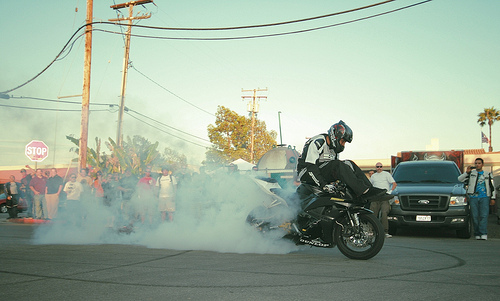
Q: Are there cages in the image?
A: No, there are no cages.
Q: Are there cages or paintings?
A: No, there are no cages or paintings.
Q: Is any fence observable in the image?
A: No, there are no fences.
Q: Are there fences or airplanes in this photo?
A: No, there are no fences or airplanes.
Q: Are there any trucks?
A: Yes, there is a truck.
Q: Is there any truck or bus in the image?
A: Yes, there is a truck.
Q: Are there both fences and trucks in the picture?
A: No, there is a truck but no fences.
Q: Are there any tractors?
A: No, there are no tractors.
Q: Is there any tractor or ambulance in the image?
A: No, there are no tractors or ambulances.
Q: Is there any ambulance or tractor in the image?
A: No, there are no tractors or ambulances.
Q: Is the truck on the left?
A: No, the truck is on the right of the image.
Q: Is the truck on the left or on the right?
A: The truck is on the right of the image.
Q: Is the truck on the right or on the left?
A: The truck is on the right of the image.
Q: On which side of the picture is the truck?
A: The truck is on the right of the image.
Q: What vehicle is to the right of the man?
A: The vehicle is a truck.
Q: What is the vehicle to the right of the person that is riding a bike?
A: The vehicle is a truck.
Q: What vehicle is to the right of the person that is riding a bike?
A: The vehicle is a truck.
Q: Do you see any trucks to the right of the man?
A: Yes, there is a truck to the right of the man.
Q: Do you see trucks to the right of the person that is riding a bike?
A: Yes, there is a truck to the right of the man.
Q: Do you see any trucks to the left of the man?
A: No, the truck is to the right of the man.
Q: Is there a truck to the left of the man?
A: No, the truck is to the right of the man.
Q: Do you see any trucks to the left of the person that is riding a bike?
A: No, the truck is to the right of the man.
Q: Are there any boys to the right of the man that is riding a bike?
A: No, there is a truck to the right of the man.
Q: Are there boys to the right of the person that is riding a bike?
A: No, there is a truck to the right of the man.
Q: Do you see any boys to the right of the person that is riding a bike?
A: No, there is a truck to the right of the man.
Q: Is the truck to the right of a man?
A: Yes, the truck is to the right of a man.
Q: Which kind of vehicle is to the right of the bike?
A: The vehicle is a truck.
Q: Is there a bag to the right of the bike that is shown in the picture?
A: No, there is a truck to the right of the bike.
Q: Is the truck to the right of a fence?
A: No, the truck is to the right of the bike.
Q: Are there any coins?
A: No, there are no coins.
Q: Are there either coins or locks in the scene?
A: No, there are no coins or locks.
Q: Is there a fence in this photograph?
A: No, there are no fences.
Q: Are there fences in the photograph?
A: No, there are no fences.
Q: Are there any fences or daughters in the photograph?
A: No, there are no fences or daughters.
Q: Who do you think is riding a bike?
A: The man is riding a bike.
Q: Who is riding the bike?
A: The man is riding a bike.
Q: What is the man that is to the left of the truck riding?
A: The man is riding a bike.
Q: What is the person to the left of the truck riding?
A: The man is riding a bike.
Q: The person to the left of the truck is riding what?
A: The man is riding a bike.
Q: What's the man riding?
A: The man is riding a bike.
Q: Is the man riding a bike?
A: Yes, the man is riding a bike.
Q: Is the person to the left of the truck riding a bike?
A: Yes, the man is riding a bike.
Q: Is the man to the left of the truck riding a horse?
A: No, the man is riding a bike.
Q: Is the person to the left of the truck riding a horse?
A: No, the man is riding a bike.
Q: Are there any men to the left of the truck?
A: Yes, there is a man to the left of the truck.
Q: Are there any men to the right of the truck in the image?
A: No, the man is to the left of the truck.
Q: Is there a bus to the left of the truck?
A: No, there is a man to the left of the truck.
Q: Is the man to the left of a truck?
A: Yes, the man is to the left of a truck.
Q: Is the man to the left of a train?
A: No, the man is to the left of a truck.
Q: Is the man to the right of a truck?
A: No, the man is to the left of a truck.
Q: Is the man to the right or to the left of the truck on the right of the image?
A: The man is to the left of the truck.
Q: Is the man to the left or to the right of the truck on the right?
A: The man is to the left of the truck.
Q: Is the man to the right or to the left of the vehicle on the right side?
A: The man is to the left of the truck.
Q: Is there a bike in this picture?
A: Yes, there is a bike.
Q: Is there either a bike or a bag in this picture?
A: Yes, there is a bike.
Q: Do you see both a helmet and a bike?
A: Yes, there are both a bike and a helmet.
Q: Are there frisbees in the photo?
A: No, there are no frisbees.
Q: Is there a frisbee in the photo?
A: No, there are no frisbees.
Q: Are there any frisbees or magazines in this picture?
A: No, there are no frisbees or magazines.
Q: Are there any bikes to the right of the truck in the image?
A: No, the bike is to the left of the truck.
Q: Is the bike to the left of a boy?
A: No, the bike is to the left of the truck.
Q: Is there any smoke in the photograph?
A: Yes, there is smoke.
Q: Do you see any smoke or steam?
A: Yes, there is smoke.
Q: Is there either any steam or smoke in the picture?
A: Yes, there is smoke.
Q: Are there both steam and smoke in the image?
A: No, there is smoke but no steam.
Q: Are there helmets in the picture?
A: Yes, there is a helmet.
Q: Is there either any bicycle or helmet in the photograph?
A: Yes, there is a helmet.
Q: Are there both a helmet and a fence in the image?
A: No, there is a helmet but no fences.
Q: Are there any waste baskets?
A: No, there are no waste baskets.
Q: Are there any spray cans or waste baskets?
A: No, there are no waste baskets or spray cans.